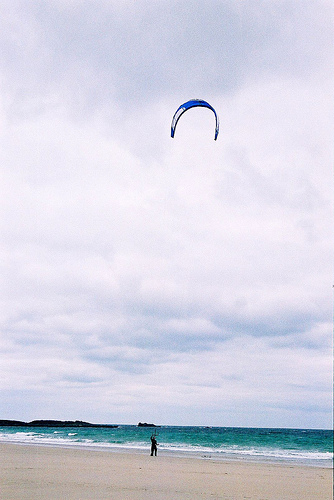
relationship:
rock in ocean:
[136, 421, 158, 426] [1, 423, 332, 461]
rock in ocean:
[0, 418, 120, 428] [1, 423, 332, 461]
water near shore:
[1, 421, 333, 471] [2, 439, 331, 497]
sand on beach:
[0, 440, 334, 498] [175, 418, 286, 493]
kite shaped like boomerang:
[166, 95, 226, 143] [168, 97, 219, 142]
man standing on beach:
[150, 434, 158, 455] [0, 437, 326, 495]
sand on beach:
[0, 440, 334, 498] [0, 437, 326, 495]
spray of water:
[2, 434, 333, 460] [2, 423, 332, 464]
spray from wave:
[2, 434, 333, 460] [5, 437, 93, 448]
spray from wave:
[2, 434, 333, 460] [104, 439, 199, 446]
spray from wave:
[2, 434, 333, 460] [228, 448, 333, 460]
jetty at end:
[0, 418, 162, 428] [0, 432, 20, 448]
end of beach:
[0, 432, 20, 448] [0, 437, 326, 495]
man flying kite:
[150, 433, 160, 456] [160, 94, 233, 147]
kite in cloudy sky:
[166, 95, 226, 143] [1, 1, 333, 429]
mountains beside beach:
[0, 418, 156, 427] [0, 437, 326, 495]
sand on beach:
[0, 440, 334, 498] [15, 365, 314, 495]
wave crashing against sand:
[1, 430, 332, 460] [0, 440, 334, 498]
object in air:
[150, 82, 248, 152] [51, 40, 161, 302]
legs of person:
[144, 449, 162, 457] [141, 428, 164, 456]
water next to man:
[1, 421, 333, 471] [148, 427, 159, 457]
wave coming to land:
[1, 430, 332, 460] [1, 440, 333, 497]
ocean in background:
[1, 423, 332, 461] [0, 416, 327, 430]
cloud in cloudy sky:
[93, 338, 150, 379] [1, 1, 333, 429]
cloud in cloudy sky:
[217, 298, 298, 335] [1, 1, 333, 429]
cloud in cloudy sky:
[155, 314, 225, 342] [1, 1, 333, 429]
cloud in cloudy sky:
[19, 250, 123, 305] [1, 1, 333, 429]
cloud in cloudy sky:
[183, 369, 223, 392] [1, 1, 333, 429]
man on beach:
[150, 433, 160, 456] [0, 441, 333, 498]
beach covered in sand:
[0, 437, 326, 495] [56, 463, 261, 494]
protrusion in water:
[136, 420, 163, 429] [1, 421, 333, 471]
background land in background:
[1, 416, 118, 426] [1, 321, 327, 433]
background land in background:
[139, 422, 155, 429] [1, 321, 327, 433]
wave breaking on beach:
[1, 430, 332, 460] [0, 437, 326, 495]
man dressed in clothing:
[150, 433, 160, 456] [150, 445, 156, 452]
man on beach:
[150, 433, 160, 456] [56, 455, 285, 496]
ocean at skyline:
[1, 423, 332, 461] [3, 404, 327, 439]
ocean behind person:
[1, 423, 332, 461] [139, 427, 168, 456]